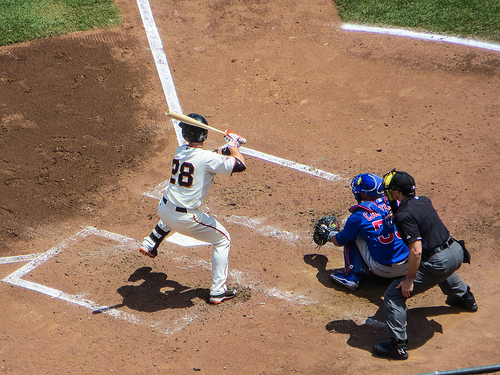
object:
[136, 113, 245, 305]
man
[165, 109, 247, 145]
bat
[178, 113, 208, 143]
helmet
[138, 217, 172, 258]
leg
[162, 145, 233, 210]
jersey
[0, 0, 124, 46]
grass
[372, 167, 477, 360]
umpire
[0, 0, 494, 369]
ground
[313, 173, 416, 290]
catcher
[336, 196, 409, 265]
jersey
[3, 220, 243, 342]
chalk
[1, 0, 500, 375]
dirt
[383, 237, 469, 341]
pants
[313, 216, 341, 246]
glove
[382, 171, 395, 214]
mask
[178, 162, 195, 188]
number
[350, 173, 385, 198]
helmet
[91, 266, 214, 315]
shadow